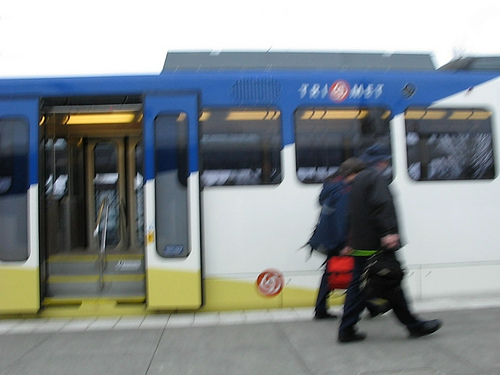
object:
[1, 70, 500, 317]
train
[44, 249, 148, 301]
entryway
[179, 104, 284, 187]
window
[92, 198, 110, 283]
rail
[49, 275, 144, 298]
step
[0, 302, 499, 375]
sidewalk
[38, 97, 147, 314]
door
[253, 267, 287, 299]
logo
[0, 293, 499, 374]
platform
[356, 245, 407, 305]
back pack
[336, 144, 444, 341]
man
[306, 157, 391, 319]
woman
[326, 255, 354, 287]
suitcase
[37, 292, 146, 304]
stairway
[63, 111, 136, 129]
lighting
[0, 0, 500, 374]
background